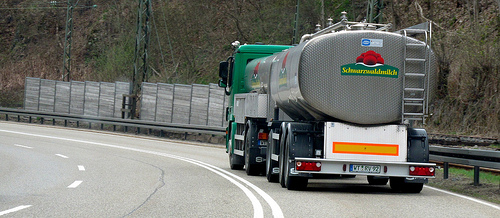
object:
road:
[0, 115, 500, 218]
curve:
[0, 129, 288, 218]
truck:
[215, 12, 442, 193]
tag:
[338, 50, 398, 78]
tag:
[323, 121, 406, 162]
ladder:
[401, 28, 429, 124]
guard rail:
[427, 145, 499, 185]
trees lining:
[123, 0, 149, 118]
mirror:
[219, 62, 229, 85]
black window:
[218, 56, 234, 96]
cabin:
[219, 45, 298, 121]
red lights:
[296, 161, 322, 171]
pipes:
[308, 22, 343, 37]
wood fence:
[25, 79, 223, 126]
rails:
[79, 117, 152, 127]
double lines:
[252, 196, 283, 218]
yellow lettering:
[341, 67, 397, 76]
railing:
[0, 106, 226, 146]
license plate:
[349, 164, 382, 174]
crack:
[149, 179, 165, 196]